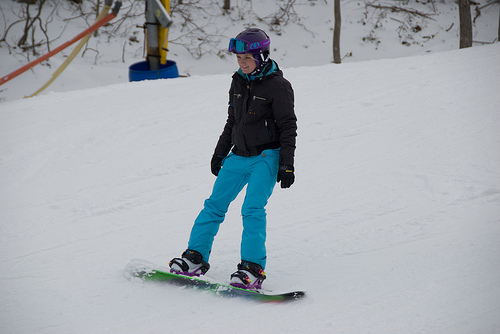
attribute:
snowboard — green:
[135, 253, 319, 307]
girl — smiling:
[198, 23, 294, 105]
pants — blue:
[198, 147, 275, 265]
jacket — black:
[215, 79, 308, 155]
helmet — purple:
[234, 28, 269, 57]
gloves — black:
[207, 154, 301, 191]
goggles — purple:
[224, 34, 278, 56]